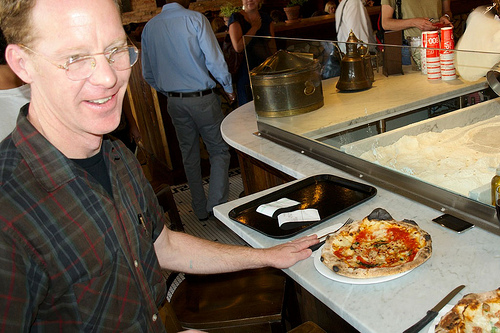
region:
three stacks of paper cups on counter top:
[413, 18, 458, 85]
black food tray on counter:
[218, 169, 378, 244]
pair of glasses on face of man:
[11, 36, 141, 86]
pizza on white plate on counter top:
[310, 206, 440, 291]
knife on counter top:
[400, 275, 469, 332]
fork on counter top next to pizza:
[308, 209, 357, 247]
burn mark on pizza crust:
[328, 260, 344, 275]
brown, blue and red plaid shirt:
[1, 98, 174, 330]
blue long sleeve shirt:
[137, 1, 237, 98]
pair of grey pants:
[161, 90, 231, 225]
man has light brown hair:
[7, 5, 48, 46]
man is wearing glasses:
[32, 39, 135, 86]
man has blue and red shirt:
[19, 141, 181, 331]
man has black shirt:
[70, 144, 118, 194]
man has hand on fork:
[280, 204, 344, 256]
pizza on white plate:
[340, 204, 415, 306]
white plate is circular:
[320, 196, 412, 303]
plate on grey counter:
[326, 201, 431, 331]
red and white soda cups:
[410, 20, 465, 100]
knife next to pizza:
[392, 266, 499, 326]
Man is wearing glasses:
[2, 3, 194, 332]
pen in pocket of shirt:
[134, 204, 153, 238]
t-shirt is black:
[55, 140, 130, 215]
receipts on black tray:
[247, 192, 324, 227]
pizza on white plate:
[306, 205, 435, 283]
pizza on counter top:
[304, 205, 443, 295]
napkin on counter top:
[297, 209, 354, 266]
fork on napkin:
[312, 215, 352, 241]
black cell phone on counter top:
[427, 207, 478, 235]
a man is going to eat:
[15, 5, 440, 326]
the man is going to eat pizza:
[193, 203, 448, 284]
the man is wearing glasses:
[38, 47, 157, 79]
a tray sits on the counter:
[226, 168, 383, 233]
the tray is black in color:
[231, 164, 376, 239]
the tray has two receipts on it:
[255, 194, 340, 236]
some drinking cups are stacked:
[416, 24, 457, 84]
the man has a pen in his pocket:
[121, 203, 158, 240]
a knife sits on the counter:
[401, 278, 469, 332]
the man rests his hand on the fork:
[273, 210, 383, 265]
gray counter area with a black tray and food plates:
[214, 170, 495, 329]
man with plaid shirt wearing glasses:
[2, 2, 325, 328]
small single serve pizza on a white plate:
[314, 216, 433, 283]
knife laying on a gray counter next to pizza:
[401, 282, 468, 330]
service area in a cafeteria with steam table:
[228, 20, 495, 219]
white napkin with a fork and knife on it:
[300, 216, 363, 254]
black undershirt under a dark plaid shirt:
[2, 104, 181, 331]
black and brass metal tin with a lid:
[244, 37, 331, 118]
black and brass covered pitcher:
[325, 31, 384, 91]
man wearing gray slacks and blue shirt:
[133, 0, 239, 220]